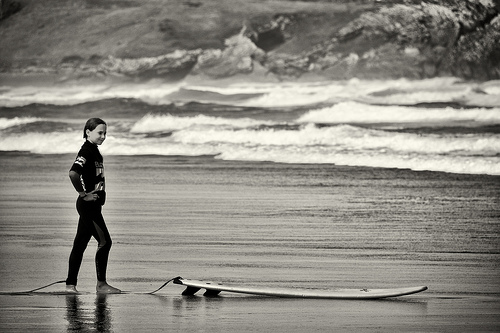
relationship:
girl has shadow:
[64, 110, 125, 302] [61, 295, 109, 333]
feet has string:
[88, 275, 126, 298] [0, 272, 71, 301]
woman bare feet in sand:
[64, 110, 125, 302] [12, 188, 476, 333]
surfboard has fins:
[165, 269, 438, 309] [174, 284, 228, 301]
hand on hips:
[77, 189, 104, 207] [73, 189, 106, 210]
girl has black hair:
[64, 110, 125, 302] [75, 111, 112, 152]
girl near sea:
[64, 110, 125, 302] [2, 1, 499, 174]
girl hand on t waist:
[64, 110, 125, 302] [73, 184, 112, 207]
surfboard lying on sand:
[165, 269, 438, 309] [12, 188, 476, 333]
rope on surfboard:
[121, 272, 184, 304] [165, 269, 438, 309]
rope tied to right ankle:
[6, 276, 78, 294] [58, 278, 83, 289]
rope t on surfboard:
[121, 272, 184, 304] [165, 269, 438, 309]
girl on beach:
[64, 110, 125, 302] [12, 188, 476, 333]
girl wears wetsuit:
[64, 110, 125, 302] [67, 144, 119, 288]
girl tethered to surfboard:
[64, 110, 125, 302] [165, 269, 438, 309]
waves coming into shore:
[2, 1, 499, 174] [12, 188, 476, 333]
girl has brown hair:
[64, 110, 125, 302] [75, 111, 112, 152]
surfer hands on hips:
[64, 110, 125, 302] [73, 189, 106, 210]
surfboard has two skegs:
[165, 269, 438, 309] [174, 284, 228, 301]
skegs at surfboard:
[174, 284, 228, 301] [165, 269, 438, 309]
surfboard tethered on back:
[165, 269, 438, 309] [0, 273, 182, 301]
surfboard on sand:
[165, 269, 438, 309] [12, 188, 476, 333]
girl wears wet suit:
[64, 110, 125, 302] [67, 144, 119, 288]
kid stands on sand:
[64, 110, 125, 302] [12, 188, 476, 333]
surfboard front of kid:
[165, 269, 438, 309] [64, 110, 125, 302]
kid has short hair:
[64, 110, 125, 302] [75, 111, 112, 152]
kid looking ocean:
[64, 110, 125, 302] [2, 1, 499, 174]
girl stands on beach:
[64, 110, 125, 302] [12, 188, 476, 333]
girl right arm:
[64, 110, 125, 302] [64, 152, 104, 204]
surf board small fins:
[165, 269, 438, 309] [174, 284, 228, 301]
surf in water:
[1, 73, 499, 174] [2, 3, 498, 331]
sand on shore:
[12, 188, 476, 333] [0, 150, 500, 330]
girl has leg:
[61, 110, 125, 301] [61, 214, 91, 296]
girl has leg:
[61, 110, 125, 301] [65, 215, 90, 294]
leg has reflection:
[61, 214, 91, 296] [61, 295, 109, 333]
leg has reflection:
[65, 215, 90, 294] [61, 295, 109, 333]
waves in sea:
[2, 1, 499, 174] [0, 1, 498, 174]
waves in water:
[2, 1, 499, 174] [2, 1, 499, 174]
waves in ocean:
[2, 1, 499, 174] [2, 1, 499, 174]